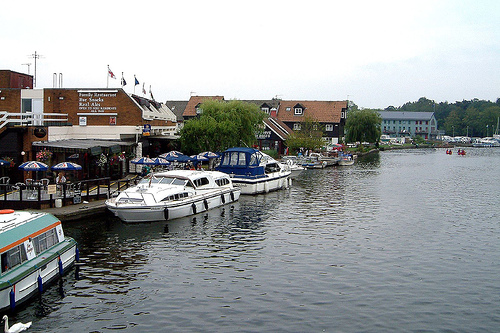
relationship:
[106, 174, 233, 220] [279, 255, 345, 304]
boat on water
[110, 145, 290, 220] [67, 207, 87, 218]
boats docked near pier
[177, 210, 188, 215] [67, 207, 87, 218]
white boat near pier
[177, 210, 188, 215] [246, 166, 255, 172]
white and blue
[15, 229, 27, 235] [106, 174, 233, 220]
green and white boat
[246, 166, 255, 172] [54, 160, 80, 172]
blue and white umbrella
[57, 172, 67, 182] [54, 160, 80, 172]
person under umbrella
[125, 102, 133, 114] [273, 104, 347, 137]
brown building in background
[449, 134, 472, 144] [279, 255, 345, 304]
cars parked near water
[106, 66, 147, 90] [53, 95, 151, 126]
flags on building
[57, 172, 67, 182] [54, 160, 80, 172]
person sitting under umbrella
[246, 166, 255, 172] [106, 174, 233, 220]
blue and white boat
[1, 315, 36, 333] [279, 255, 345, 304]
swan in water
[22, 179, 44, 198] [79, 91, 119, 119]
seating at restaurant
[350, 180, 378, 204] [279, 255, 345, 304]
ripple in water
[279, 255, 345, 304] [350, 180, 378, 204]
water with a ripple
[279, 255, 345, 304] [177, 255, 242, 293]
water has ripples